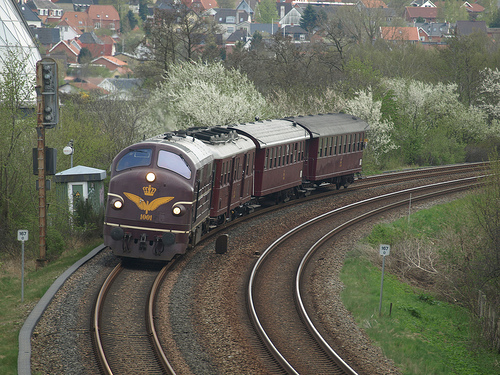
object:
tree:
[382, 72, 463, 166]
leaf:
[445, 54, 456, 67]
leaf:
[470, 108, 481, 115]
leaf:
[413, 81, 427, 89]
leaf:
[421, 109, 429, 122]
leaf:
[435, 130, 448, 139]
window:
[155, 148, 192, 179]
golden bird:
[121, 187, 175, 215]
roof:
[88, 54, 125, 64]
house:
[89, 55, 128, 69]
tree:
[142, 56, 271, 127]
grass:
[342, 184, 500, 374]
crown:
[142, 184, 157, 200]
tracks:
[92, 162, 500, 374]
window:
[115, 149, 152, 171]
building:
[50, 163, 109, 235]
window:
[284, 143, 292, 156]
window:
[356, 132, 364, 144]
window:
[352, 139, 356, 155]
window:
[268, 159, 275, 171]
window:
[277, 157, 284, 166]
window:
[295, 153, 299, 160]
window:
[334, 146, 339, 157]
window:
[357, 142, 363, 152]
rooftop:
[401, 6, 445, 16]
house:
[404, 6, 450, 22]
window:
[225, 171, 229, 188]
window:
[268, 157, 274, 171]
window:
[271, 145, 279, 159]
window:
[284, 152, 289, 168]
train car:
[102, 109, 370, 262]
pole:
[18, 240, 27, 300]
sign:
[18, 227, 29, 242]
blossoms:
[194, 82, 216, 93]